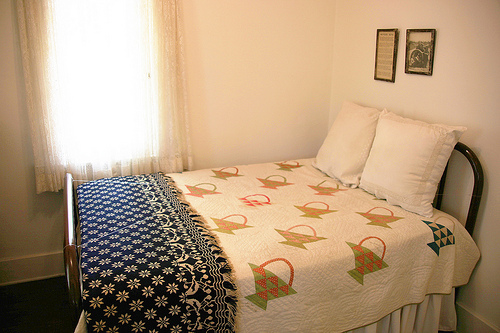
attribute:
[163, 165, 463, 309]
quilt — multi-colored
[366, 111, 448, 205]
pillow — white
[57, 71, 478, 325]
bed — iron, large, made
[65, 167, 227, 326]
blanket — daisy patterned, blue, white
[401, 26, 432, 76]
picture — black, white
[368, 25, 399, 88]
picture — old, framed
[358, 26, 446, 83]
pictures — old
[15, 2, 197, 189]
curtains — white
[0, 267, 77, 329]
carpet — blue, dark blue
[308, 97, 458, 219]
pillows — white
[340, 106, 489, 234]
frame — brass, iron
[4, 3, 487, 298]
walls — white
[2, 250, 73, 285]
trim — white